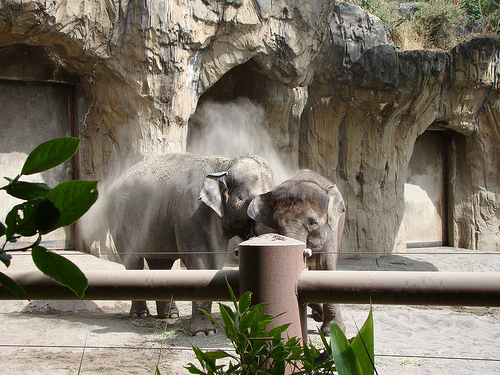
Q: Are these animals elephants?
A: Yes, all the animals are elephants.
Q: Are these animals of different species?
A: No, all the animals are elephants.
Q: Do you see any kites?
A: No, there are no kites.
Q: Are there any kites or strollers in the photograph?
A: No, there are no kites or strollers.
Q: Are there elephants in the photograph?
A: Yes, there is an elephant.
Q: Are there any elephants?
A: Yes, there is an elephant.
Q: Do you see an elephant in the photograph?
A: Yes, there is an elephant.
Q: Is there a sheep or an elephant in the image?
A: Yes, there is an elephant.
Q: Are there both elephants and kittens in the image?
A: No, there is an elephant but no kittens.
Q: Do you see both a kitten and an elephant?
A: No, there is an elephant but no kittens.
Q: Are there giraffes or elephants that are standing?
A: Yes, the elephant is standing.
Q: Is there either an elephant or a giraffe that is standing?
A: Yes, the elephant is standing.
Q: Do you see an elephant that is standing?
A: Yes, there is an elephant that is standing.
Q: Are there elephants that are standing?
A: Yes, there is an elephant that is standing.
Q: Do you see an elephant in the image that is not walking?
A: Yes, there is an elephant that is standing .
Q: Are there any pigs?
A: No, there are no pigs.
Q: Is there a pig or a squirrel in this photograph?
A: No, there are no pigs or squirrels.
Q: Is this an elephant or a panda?
A: This is an elephant.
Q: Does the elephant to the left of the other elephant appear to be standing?
A: Yes, the elephant is standing.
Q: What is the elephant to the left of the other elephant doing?
A: The elephant is standing.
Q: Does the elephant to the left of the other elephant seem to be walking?
A: No, the elephant is standing.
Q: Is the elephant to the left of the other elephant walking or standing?
A: The elephant is standing.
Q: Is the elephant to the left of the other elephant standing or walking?
A: The elephant is standing.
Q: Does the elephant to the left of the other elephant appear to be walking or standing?
A: The elephant is standing.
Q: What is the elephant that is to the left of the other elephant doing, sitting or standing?
A: The elephant is standing.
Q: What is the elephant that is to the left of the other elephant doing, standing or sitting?
A: The elephant is standing.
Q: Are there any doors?
A: Yes, there is a door.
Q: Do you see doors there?
A: Yes, there is a door.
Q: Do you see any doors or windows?
A: Yes, there is a door.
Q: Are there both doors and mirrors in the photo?
A: No, there is a door but no mirrors.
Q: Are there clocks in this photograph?
A: No, there are no clocks.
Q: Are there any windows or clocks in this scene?
A: No, there are no clocks or windows.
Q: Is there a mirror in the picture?
A: No, there are no mirrors.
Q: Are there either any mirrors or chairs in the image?
A: No, there are no mirrors or chairs.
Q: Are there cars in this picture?
A: No, there are no cars.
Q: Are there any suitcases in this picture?
A: No, there are no suitcases.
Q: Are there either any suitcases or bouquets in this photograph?
A: No, there are no suitcases or bouquets.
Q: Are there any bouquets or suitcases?
A: No, there are no suitcases or bouquets.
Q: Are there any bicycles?
A: No, there are no bicycles.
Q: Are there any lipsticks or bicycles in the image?
A: No, there are no bicycles or lipsticks.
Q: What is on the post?
A: The dirt is on the post.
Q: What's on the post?
A: The dirt is on the post.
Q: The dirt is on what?
A: The dirt is on the post.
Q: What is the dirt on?
A: The dirt is on the post.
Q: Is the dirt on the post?
A: Yes, the dirt is on the post.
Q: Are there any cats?
A: No, there are no cats.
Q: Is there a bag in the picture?
A: No, there are no bags.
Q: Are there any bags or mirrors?
A: No, there are no bags or mirrors.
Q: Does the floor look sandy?
A: Yes, the floor is sandy.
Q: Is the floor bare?
A: No, the floor is sandy.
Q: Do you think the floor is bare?
A: No, the floor is sandy.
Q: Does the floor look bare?
A: No, the floor is sandy.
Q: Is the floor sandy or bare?
A: The floor is sandy.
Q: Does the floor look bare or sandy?
A: The floor is sandy.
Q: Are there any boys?
A: No, there are no boys.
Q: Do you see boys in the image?
A: No, there are no boys.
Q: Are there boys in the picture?
A: No, there are no boys.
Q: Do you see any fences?
A: Yes, there is a fence.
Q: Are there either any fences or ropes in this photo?
A: Yes, there is a fence.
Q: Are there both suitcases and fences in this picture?
A: No, there is a fence but no suitcases.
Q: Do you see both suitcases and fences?
A: No, there is a fence but no suitcases.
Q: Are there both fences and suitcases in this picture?
A: No, there is a fence but no suitcases.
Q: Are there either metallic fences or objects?
A: Yes, there is a metal fence.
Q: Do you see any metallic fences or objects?
A: Yes, there is a metal fence.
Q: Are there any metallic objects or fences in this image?
A: Yes, there is a metal fence.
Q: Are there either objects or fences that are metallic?
A: Yes, the fence is metallic.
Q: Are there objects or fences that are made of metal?
A: Yes, the fence is made of metal.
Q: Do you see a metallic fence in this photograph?
A: Yes, there is a metal fence.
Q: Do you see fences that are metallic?
A: Yes, there is a fence that is metallic.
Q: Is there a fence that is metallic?
A: Yes, there is a fence that is metallic.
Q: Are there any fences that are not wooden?
A: Yes, there is a metallic fence.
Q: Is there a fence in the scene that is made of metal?
A: Yes, there is a fence that is made of metal.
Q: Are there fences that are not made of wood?
A: Yes, there is a fence that is made of metal.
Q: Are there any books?
A: No, there are no books.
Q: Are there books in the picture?
A: No, there are no books.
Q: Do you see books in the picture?
A: No, there are no books.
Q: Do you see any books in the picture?
A: No, there are no books.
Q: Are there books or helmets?
A: No, there are no books or helmets.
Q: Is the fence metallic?
A: Yes, the fence is metallic.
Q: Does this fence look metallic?
A: Yes, the fence is metallic.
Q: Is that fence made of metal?
A: Yes, the fence is made of metal.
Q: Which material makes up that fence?
A: The fence is made of metal.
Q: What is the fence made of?
A: The fence is made of metal.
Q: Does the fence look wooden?
A: No, the fence is metallic.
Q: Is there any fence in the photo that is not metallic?
A: No, there is a fence but it is metallic.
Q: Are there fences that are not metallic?
A: No, there is a fence but it is metallic.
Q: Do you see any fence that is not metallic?
A: No, there is a fence but it is metallic.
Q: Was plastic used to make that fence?
A: No, the fence is made of metal.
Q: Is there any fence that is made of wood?
A: No, there is a fence but it is made of metal.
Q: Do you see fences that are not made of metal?
A: No, there is a fence but it is made of metal.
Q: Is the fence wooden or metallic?
A: The fence is metallic.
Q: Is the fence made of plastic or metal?
A: The fence is made of metal.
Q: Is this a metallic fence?
A: Yes, this is a metallic fence.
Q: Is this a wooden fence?
A: No, this is a metallic fence.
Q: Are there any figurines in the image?
A: No, there are no figurines.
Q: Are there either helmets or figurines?
A: No, there are no figurines or helmets.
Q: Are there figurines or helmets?
A: No, there are no figurines or helmets.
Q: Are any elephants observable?
A: Yes, there is an elephant.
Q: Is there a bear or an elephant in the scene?
A: Yes, there is an elephant.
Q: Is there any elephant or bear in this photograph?
A: Yes, there is an elephant.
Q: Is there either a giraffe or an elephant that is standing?
A: Yes, the elephant is standing.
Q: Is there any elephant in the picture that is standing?
A: Yes, there is an elephant that is standing.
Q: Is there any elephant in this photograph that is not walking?
A: Yes, there is an elephant that is standing.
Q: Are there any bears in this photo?
A: No, there are no bears.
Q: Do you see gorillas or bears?
A: No, there are no bears or gorillas.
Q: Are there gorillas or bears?
A: No, there are no bears or gorillas.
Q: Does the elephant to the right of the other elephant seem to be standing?
A: Yes, the elephant is standing.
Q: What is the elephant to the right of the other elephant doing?
A: The elephant is standing.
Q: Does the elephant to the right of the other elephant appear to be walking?
A: No, the elephant is standing.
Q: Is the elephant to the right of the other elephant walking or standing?
A: The elephant is standing.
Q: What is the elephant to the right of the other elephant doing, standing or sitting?
A: The elephant is standing.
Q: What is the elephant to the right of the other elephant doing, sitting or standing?
A: The elephant is standing.